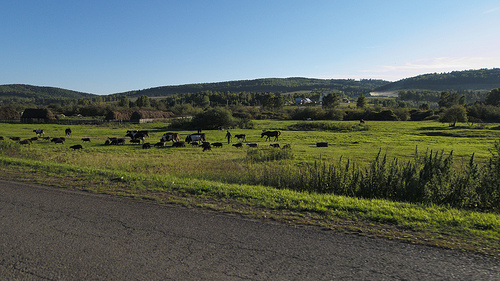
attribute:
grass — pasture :
[0, 114, 495, 258]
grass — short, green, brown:
[69, 187, 497, 230]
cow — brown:
[258, 128, 285, 139]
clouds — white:
[359, 55, 437, 73]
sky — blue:
[4, 3, 499, 69]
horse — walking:
[258, 127, 282, 140]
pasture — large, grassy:
[10, 117, 494, 178]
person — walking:
[220, 126, 234, 146]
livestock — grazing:
[14, 125, 221, 152]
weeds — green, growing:
[262, 158, 490, 200]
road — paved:
[12, 178, 291, 276]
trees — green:
[331, 101, 478, 122]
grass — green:
[27, 126, 499, 182]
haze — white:
[272, 27, 498, 75]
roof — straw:
[25, 107, 59, 117]